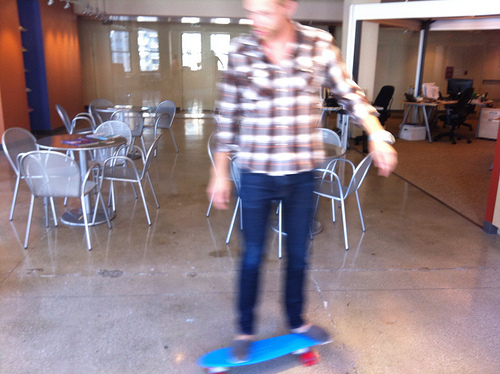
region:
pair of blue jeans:
[232, 165, 319, 336]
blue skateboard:
[191, 320, 341, 372]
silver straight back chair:
[88, 128, 163, 234]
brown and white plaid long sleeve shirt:
[208, 23, 380, 179]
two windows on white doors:
[178, 28, 237, 113]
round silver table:
[35, 125, 129, 232]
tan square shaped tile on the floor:
[314, 263, 499, 302]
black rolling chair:
[436, 85, 476, 154]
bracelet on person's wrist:
[356, 121, 398, 148]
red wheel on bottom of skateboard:
[300, 340, 320, 372]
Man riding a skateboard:
[194, 0, 400, 370]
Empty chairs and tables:
[1, 95, 177, 252]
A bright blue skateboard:
[190, 322, 332, 371]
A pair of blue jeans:
[235, 167, 319, 334]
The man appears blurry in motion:
[201, 0, 400, 215]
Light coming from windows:
[109, 14, 253, 73]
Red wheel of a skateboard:
[296, 347, 319, 369]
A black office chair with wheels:
[435, 83, 482, 148]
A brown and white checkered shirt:
[212, 22, 380, 179]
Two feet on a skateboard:
[196, 319, 333, 372]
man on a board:
[162, 3, 389, 325]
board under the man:
[198, 304, 338, 372]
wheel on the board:
[295, 343, 325, 372]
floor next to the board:
[62, 299, 167, 359]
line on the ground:
[107, 267, 167, 326]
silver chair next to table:
[83, 128, 174, 241]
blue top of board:
[211, 314, 325, 371]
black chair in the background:
[428, 84, 480, 147]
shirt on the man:
[214, 35, 359, 160]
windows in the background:
[92, 18, 202, 78]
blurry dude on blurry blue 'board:
[185, 0, 408, 371]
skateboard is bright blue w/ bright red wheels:
[192, 322, 334, 372]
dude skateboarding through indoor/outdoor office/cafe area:
[1, 0, 496, 370]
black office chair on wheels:
[430, 83, 482, 148]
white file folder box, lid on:
[394, 121, 429, 143]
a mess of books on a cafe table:
[56, 124, 121, 152]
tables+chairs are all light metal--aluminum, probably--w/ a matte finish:
[0, 90, 380, 275]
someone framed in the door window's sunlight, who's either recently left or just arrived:
[206, 32, 224, 68]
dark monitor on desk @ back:
[445, 75, 475, 101]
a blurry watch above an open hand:
[364, 126, 399, 145]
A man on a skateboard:
[205, 0, 402, 362]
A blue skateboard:
[196, 327, 320, 372]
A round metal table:
[36, 131, 131, 225]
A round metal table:
[94, 103, 149, 161]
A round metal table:
[270, 142, 345, 237]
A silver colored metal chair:
[91, 128, 163, 227]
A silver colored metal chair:
[24, 151, 114, 251]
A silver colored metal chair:
[0, 129, 82, 226]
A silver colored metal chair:
[309, 149, 374, 254]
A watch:
[369, 129, 394, 144]